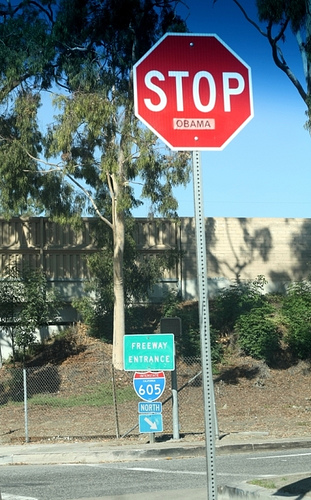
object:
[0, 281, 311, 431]
hill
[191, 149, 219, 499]
pole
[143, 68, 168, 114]
letter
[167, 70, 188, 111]
letter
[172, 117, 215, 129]
letter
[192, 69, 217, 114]
letter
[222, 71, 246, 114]
letter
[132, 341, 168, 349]
letter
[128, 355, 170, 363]
letter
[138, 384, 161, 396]
letter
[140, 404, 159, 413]
letter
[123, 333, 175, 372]
sign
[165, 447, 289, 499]
corner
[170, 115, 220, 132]
sticker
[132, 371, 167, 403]
sign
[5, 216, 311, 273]
wall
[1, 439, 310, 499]
road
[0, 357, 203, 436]
fence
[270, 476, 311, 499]
shadow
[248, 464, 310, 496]
grass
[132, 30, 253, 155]
sign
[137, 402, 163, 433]
sign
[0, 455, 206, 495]
sidewalk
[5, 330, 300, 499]
intersection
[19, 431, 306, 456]
curb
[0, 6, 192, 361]
trees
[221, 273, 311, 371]
shrubs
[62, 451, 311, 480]
lines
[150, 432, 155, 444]
pole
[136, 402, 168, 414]
sign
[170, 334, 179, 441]
pole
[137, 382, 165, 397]
name